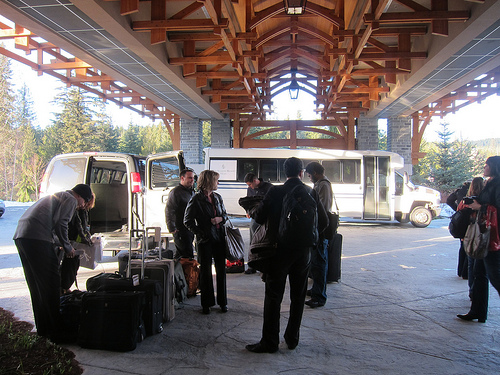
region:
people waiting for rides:
[15, 156, 497, 363]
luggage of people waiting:
[64, 216, 201, 348]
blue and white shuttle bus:
[199, 146, 445, 224]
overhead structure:
[32, 60, 494, 130]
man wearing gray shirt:
[14, 176, 98, 335]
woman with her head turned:
[185, 166, 235, 318]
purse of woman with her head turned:
[222, 209, 249, 262]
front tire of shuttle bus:
[405, 200, 430, 226]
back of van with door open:
[41, 150, 136, 249]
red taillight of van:
[126, 169, 144, 196]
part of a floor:
[347, 222, 394, 329]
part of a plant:
[26, 328, 69, 364]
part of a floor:
[326, 295, 371, 360]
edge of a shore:
[246, 337, 281, 355]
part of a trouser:
[252, 265, 281, 315]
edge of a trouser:
[284, 288, 310, 349]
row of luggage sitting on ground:
[55, 222, 182, 348]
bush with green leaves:
[0, 317, 82, 372]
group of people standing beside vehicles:
[20, 103, 497, 373]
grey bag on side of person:
[222, 224, 249, 266]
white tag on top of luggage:
[128, 270, 143, 292]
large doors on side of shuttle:
[355, 150, 399, 230]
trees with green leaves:
[50, 87, 100, 153]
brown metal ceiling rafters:
[165, 2, 257, 99]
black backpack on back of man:
[270, 175, 332, 254]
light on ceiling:
[278, 2, 305, 22]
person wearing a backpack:
[272, 186, 318, 257]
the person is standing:
[259, 179, 326, 340]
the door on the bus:
[361, 158, 398, 226]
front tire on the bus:
[410, 208, 428, 226]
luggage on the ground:
[87, 270, 156, 338]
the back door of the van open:
[147, 158, 167, 222]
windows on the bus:
[322, 160, 357, 183]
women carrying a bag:
[217, 213, 247, 263]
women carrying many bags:
[455, 206, 486, 260]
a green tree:
[435, 131, 467, 194]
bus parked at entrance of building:
[193, 126, 463, 233]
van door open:
[41, 124, 240, 274]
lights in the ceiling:
[285, 4, 310, 105]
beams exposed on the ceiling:
[160, 7, 389, 102]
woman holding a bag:
[189, 173, 260, 279]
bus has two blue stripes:
[196, 160, 253, 194]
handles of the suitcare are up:
[123, 224, 178, 289]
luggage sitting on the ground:
[99, 221, 212, 359]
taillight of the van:
[126, 172, 155, 195]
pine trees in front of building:
[28, 96, 97, 197]